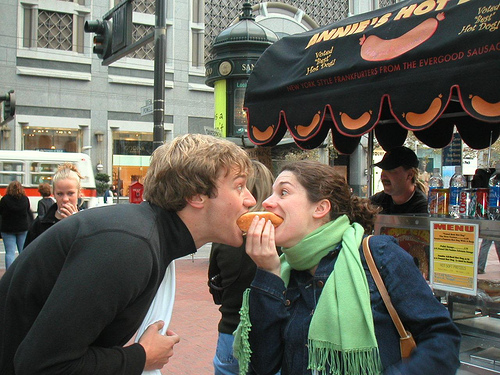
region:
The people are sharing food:
[210, 182, 303, 269]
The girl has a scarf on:
[271, 221, 394, 371]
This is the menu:
[418, 210, 487, 302]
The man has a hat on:
[364, 145, 419, 177]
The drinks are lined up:
[421, 162, 499, 228]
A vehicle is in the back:
[0, 145, 102, 207]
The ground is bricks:
[184, 277, 207, 372]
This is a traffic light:
[72, 12, 128, 77]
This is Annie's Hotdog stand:
[280, 0, 470, 66]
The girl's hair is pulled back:
[282, 152, 394, 241]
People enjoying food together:
[125, 130, 355, 265]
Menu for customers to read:
[425, 215, 480, 305]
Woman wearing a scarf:
[261, 150, 406, 370]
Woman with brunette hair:
[260, 156, 371, 241]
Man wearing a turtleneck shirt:
[0, 121, 250, 371]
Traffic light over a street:
[75, 2, 145, 62]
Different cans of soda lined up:
[420, 181, 495, 216]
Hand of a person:
[126, 316, 181, 372]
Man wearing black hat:
[365, 140, 435, 211]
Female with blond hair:
[40, 161, 85, 207]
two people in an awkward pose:
[111, 116, 402, 297]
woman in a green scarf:
[230, 156, 415, 374]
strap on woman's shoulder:
[349, 227, 429, 326]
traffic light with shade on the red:
[76, 6, 133, 62]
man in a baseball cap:
[351, 138, 437, 270]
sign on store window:
[421, 221, 485, 301]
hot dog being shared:
[205, 192, 303, 239]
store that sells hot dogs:
[260, 0, 495, 374]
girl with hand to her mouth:
[26, 160, 101, 245]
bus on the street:
[0, 136, 114, 233]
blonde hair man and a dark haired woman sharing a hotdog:
[0, 133, 461, 373]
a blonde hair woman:
[21, 159, 101, 244]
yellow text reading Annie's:
[301, 10, 391, 46]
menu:
[431, 219, 478, 296]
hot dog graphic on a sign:
[347, 12, 462, 62]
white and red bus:
[1, 148, 96, 206]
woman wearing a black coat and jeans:
[1, 178, 33, 261]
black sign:
[238, 0, 498, 140]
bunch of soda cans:
[424, 185, 498, 215]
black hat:
[371, 143, 421, 170]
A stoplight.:
[77, 0, 172, 135]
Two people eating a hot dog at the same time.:
[7, 135, 447, 371]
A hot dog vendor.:
[242, 0, 492, 285]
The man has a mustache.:
[365, 140, 430, 205]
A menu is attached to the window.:
[425, 216, 485, 306]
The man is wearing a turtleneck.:
[2, 125, 252, 370]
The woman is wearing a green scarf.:
[256, 160, 383, 370]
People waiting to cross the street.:
[0, 170, 50, 240]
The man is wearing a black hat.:
[365, 145, 420, 206]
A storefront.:
[90, 108, 158, 199]